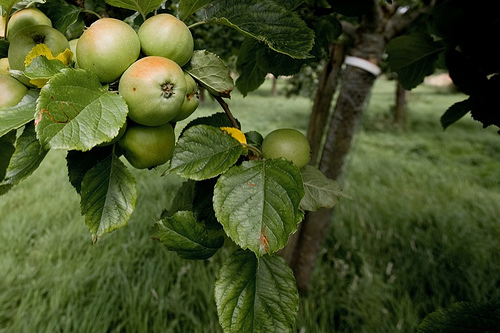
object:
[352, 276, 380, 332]
grass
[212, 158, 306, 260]
leaf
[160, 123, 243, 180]
leaf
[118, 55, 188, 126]
fruit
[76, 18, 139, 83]
fruit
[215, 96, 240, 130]
branch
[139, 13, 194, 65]
apple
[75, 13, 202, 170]
bunch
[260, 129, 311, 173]
apple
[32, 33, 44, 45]
stem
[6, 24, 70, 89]
apple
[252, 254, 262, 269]
tip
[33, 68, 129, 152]
leaf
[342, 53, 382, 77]
band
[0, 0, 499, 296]
tree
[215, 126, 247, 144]
leaff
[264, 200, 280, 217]
vein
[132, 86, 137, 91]
spot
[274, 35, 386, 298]
trunk